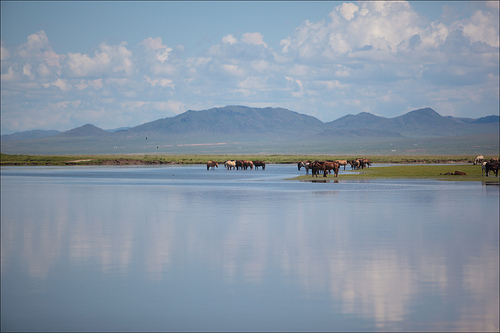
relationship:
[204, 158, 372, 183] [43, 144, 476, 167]
horse group standing in forest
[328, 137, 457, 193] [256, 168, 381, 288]
grass near water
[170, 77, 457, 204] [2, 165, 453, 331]
mountain near river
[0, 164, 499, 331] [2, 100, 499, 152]
river near mountain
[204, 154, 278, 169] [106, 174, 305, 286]
animals standing inside river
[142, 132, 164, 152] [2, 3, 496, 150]
birds flying in air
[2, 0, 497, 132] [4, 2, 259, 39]
clouds in blue sky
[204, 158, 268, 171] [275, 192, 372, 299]
animals drinking water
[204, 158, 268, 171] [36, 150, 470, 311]
animals standing in water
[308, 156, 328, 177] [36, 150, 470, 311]
horse standing next to water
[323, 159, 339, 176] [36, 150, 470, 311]
horse standing next to water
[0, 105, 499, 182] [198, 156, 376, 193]
land in horses water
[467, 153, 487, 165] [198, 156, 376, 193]
white horse next to horses water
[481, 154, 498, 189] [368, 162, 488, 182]
horse laying on ground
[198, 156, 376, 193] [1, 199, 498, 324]
horses water has reflection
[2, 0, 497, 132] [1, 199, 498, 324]
clouds have reflection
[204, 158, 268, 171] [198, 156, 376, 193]
animals in horses water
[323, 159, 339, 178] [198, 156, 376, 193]
horse in horses water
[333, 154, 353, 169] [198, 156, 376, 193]
horse in horses water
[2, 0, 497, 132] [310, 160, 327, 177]
clouds over horse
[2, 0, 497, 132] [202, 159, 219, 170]
clouds over horse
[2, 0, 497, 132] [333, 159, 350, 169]
clouds over horse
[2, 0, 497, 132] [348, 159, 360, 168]
clouds over horse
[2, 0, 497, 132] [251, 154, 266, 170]
clouds over horse